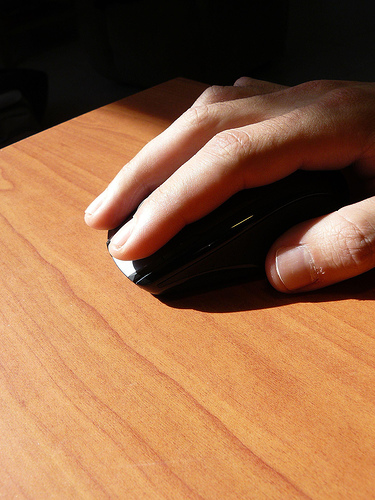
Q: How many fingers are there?
A: Five.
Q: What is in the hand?
A: A computer mouse.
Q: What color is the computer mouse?
A: Black.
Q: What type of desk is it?
A: Wooden.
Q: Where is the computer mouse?
A: In a hand.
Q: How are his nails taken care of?
A: They're manicured.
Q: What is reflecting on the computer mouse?
A: Light.